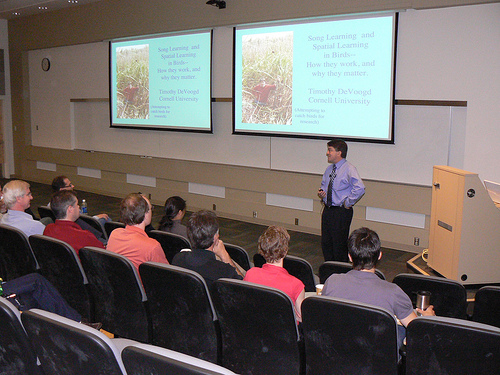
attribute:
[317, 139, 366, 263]
man — lecturing, presenting, speaking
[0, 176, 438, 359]
people — listening, attentive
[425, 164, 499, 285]
podium — tan , wooden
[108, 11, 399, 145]
slide show — digital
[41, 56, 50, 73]
clock — analog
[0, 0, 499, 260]
wall — white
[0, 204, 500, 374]
seats — cushioned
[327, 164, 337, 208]
purple tie — shiny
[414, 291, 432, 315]
thermos — metal, silver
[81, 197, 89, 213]
water bottle — plastic